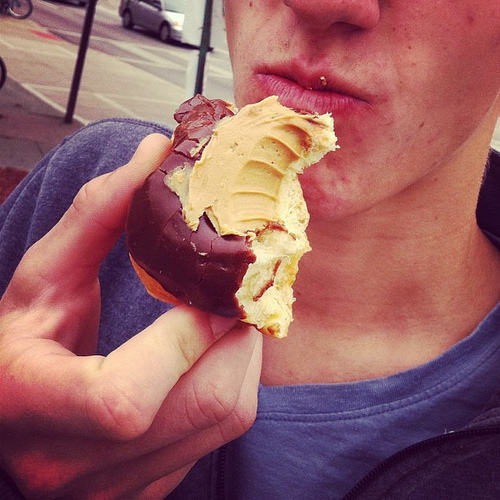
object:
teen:
[2, 2, 499, 499]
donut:
[125, 94, 338, 336]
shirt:
[4, 115, 499, 500]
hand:
[1, 133, 263, 498]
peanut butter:
[170, 92, 322, 238]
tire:
[7, 1, 32, 16]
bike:
[0, 0, 34, 20]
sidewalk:
[0, 65, 79, 195]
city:
[4, 1, 500, 229]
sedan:
[118, 1, 182, 41]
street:
[0, 0, 251, 122]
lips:
[252, 77, 369, 121]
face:
[221, 0, 500, 215]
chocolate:
[127, 93, 246, 319]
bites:
[241, 109, 333, 155]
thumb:
[37, 133, 166, 268]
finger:
[25, 302, 233, 441]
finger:
[40, 329, 255, 487]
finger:
[119, 335, 264, 491]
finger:
[139, 464, 202, 498]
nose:
[284, 0, 382, 29]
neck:
[249, 130, 500, 305]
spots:
[320, 76, 324, 79]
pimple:
[466, 15, 476, 29]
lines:
[248, 156, 284, 175]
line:
[281, 121, 311, 143]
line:
[263, 135, 302, 159]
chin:
[299, 163, 363, 219]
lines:
[4, 71, 93, 127]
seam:
[188, 304, 494, 417]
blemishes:
[224, 137, 244, 153]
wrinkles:
[88, 406, 109, 442]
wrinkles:
[186, 383, 209, 426]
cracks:
[186, 135, 201, 144]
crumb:
[308, 87, 313, 91]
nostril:
[334, 23, 360, 36]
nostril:
[282, 4, 297, 18]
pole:
[191, 1, 218, 96]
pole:
[63, 0, 98, 124]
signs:
[179, 0, 234, 52]